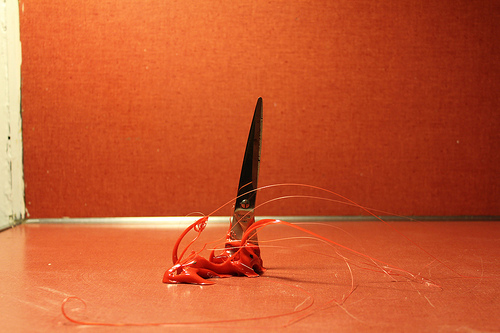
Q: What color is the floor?
A: Orange.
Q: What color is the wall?
A: Burnt orange.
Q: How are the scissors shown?
A: Buried.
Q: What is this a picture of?
A: An art installation.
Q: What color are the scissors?
A: Silver.